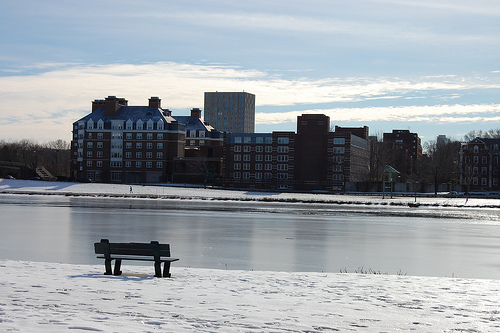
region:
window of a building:
[234, 141, 241, 156]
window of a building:
[83, 132, 94, 139]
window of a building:
[112, 130, 123, 144]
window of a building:
[128, 130, 133, 139]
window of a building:
[332, 136, 347, 145]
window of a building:
[274, 132, 288, 146]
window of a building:
[276, 170, 290, 178]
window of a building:
[229, 164, 242, 170]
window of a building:
[242, 162, 252, 170]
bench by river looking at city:
[88, 233, 182, 273]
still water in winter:
[4, 195, 494, 276]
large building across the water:
[68, 95, 210, 186]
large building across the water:
[231, 129, 299, 184]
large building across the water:
[295, 113, 375, 195]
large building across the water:
[200, 88, 256, 133]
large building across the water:
[385, 133, 418, 184]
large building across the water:
[455, 138, 497, 188]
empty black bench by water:
[88, 240, 178, 276]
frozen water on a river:
[202, 207, 488, 297]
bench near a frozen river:
[86, 224, 223, 293]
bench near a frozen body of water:
[90, 215, 296, 319]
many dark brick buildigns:
[77, 92, 490, 208]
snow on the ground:
[225, 260, 434, 312]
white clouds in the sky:
[59, 14, 412, 82]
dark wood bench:
[94, 232, 176, 279]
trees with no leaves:
[18, 140, 71, 162]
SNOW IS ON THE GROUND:
[76, 63, 334, 312]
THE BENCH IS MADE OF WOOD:
[77, 221, 255, 302]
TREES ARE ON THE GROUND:
[353, 149, 471, 233]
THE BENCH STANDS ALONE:
[77, 227, 132, 280]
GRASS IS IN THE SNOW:
[315, 239, 485, 289]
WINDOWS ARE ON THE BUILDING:
[222, 133, 414, 264]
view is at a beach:
[59, 138, 424, 332]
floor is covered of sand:
[256, 283, 308, 330]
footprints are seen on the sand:
[75, 268, 175, 330]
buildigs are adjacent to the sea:
[84, 91, 332, 190]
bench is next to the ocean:
[89, 202, 233, 310]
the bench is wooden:
[88, 219, 185, 299]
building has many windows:
[83, 102, 204, 176]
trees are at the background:
[17, 127, 82, 205]